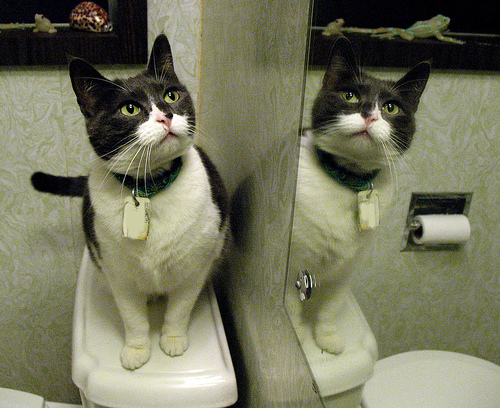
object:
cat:
[30, 29, 231, 371]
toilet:
[68, 243, 236, 408]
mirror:
[283, 0, 500, 408]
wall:
[201, 0, 300, 109]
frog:
[368, 13, 465, 45]